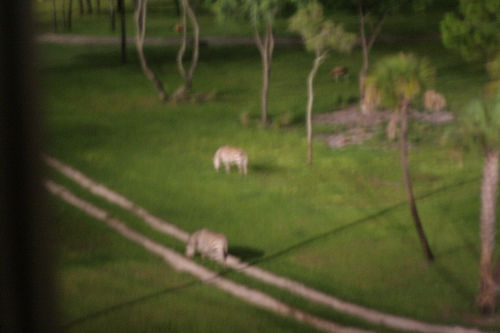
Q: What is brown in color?
A: The logs.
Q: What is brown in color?
A: Tree trunk.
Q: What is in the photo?
A: Animals.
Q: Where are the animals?
A: On the grass.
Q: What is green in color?
A: Grass.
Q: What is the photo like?
A: Fuzzy.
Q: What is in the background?
A: Sidewalk.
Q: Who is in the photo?
A: No people.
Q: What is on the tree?
A: A branch.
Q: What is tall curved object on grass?
A: Tree.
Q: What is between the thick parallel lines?
A: Animal.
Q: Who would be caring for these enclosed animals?
A: Zookeeper.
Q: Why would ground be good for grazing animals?
A: Green grass.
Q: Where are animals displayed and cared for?
A: Zoo.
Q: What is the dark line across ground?
A: Shadow of wire.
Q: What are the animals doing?
A: Grazing.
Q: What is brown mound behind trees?
A: Dirt and rocks.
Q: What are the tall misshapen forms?
A: Tree trunks.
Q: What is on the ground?
A: Shadows.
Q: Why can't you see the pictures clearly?
A: It's blurry.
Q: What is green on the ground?
A: Grass.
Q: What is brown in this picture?
A: The animals.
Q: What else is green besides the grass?
A: The leaves.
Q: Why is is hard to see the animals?
A: Picture is blurry.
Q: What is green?
A: Grass.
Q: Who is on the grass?
A: Animals.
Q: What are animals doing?
A: Grazing.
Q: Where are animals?
A: On the grass.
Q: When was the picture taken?
A: Night.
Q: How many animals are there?
A: Two.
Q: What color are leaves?
A: Green.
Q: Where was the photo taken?
A: Above a wildlife preserve.